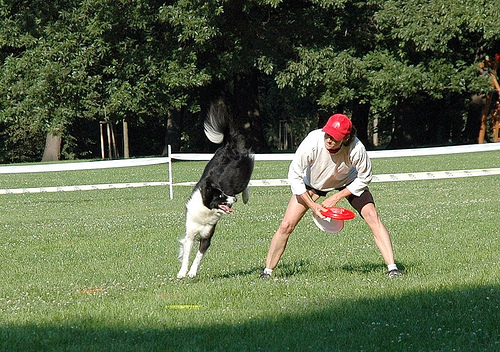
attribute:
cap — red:
[323, 112, 351, 142]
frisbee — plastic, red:
[321, 207, 356, 221]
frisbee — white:
[314, 212, 345, 236]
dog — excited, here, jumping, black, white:
[175, 96, 255, 279]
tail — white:
[203, 96, 248, 151]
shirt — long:
[289, 127, 373, 198]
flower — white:
[376, 295, 500, 351]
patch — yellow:
[166, 303, 204, 310]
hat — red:
[321, 113, 354, 141]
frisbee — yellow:
[167, 303, 203, 309]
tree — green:
[0, 1, 499, 164]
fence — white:
[1, 143, 499, 195]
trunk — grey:
[42, 124, 62, 162]